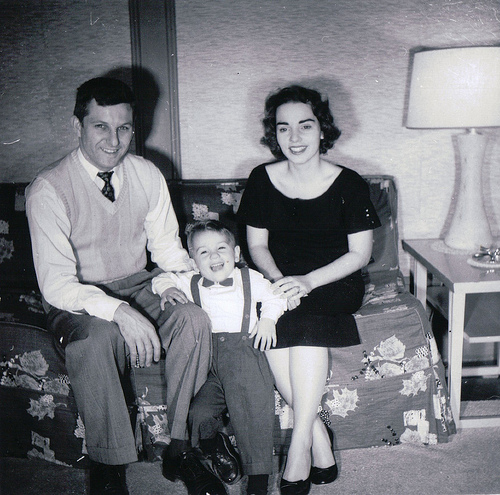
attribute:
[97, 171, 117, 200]
tie — black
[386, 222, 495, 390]
table — end table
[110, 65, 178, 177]
shadow — man's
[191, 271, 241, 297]
bowtie — black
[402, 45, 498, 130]
lamp shade — white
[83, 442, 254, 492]
shoes — black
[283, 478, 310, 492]
shoe — black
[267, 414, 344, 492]
shoes — Black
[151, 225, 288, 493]
boy — little